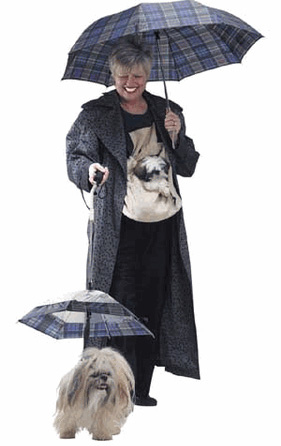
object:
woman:
[65, 44, 201, 407]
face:
[114, 69, 146, 101]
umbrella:
[59, 0, 265, 150]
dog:
[51, 343, 136, 441]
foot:
[56, 430, 77, 438]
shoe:
[133, 394, 159, 407]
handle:
[154, 36, 181, 141]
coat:
[64, 88, 200, 383]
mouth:
[90, 380, 110, 392]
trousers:
[108, 217, 178, 402]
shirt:
[116, 94, 186, 227]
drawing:
[121, 120, 184, 225]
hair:
[68, 343, 137, 438]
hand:
[84, 162, 116, 192]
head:
[105, 37, 157, 103]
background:
[0, 1, 281, 446]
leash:
[82, 191, 99, 350]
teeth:
[126, 88, 137, 91]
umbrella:
[15, 282, 157, 353]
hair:
[108, 36, 153, 79]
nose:
[99, 373, 111, 385]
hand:
[161, 108, 182, 139]